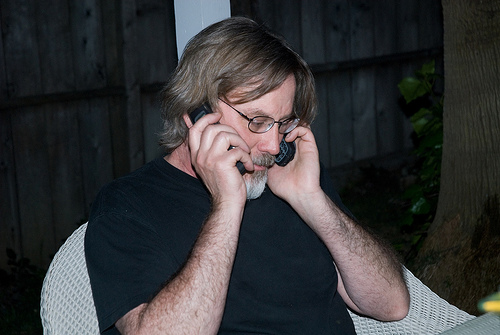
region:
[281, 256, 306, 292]
part of a shirt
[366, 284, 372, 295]
part of an arm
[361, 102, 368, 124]
part of a board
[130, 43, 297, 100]
man has brown hair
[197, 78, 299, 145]
man has black glasses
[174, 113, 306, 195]
man holds two phones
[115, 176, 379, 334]
man has black shirt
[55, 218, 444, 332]
man sits in white chair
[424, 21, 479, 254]
brown trunk of tree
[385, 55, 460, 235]
green leaves behind tree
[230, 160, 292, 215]
man has white beard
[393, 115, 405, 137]
part of a board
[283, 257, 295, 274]
part of a shirt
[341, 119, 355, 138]
part of a board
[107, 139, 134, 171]
edge of a board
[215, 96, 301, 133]
black frame reading glasses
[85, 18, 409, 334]
the man is using his 2 mobile phones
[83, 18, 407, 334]
the man is talking on his celphones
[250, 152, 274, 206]
the man has a mustache and a beard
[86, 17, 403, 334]
the man is wearing a black t shirt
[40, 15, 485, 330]
the man is sitting on the white chair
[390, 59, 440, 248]
green leaf plants on the ground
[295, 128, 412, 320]
white hairy arm of a man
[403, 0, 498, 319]
truck of a tree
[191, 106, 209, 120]
a black telephone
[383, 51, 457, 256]
green leaves behind tree trunk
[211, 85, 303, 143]
eye glasses on man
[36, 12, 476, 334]
man sitting in chair and holding one cell phone to each ear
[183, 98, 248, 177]
black cell phone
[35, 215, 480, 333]
white wicker chair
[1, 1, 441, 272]
brown wood slat fence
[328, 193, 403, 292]
brown hair on man's arm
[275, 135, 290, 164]
black buttons on face of cell phone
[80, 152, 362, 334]
black short sleeve t-shirt on man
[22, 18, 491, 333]
a man on the phone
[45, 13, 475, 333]
a person sitting down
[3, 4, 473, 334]
a scene outside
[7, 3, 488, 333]
a scene during the night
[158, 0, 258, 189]
a white post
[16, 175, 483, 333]
a white chair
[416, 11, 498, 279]
a tree in the background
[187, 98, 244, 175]
person holding black cell phone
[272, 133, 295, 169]
person holding black cell phone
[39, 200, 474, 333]
white wicker chair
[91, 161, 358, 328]
short sleeve black shirt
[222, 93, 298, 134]
black wire rimmed glasses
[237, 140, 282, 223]
white and brown beard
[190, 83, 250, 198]
black phone in hand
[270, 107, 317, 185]
black phone in hand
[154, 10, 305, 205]
shaggy brown hair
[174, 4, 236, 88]
white square post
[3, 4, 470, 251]
brown wooden fence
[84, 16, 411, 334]
white man on phone sitting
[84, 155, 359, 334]
short sleeved black cloth shirt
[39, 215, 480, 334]
large white cloth chair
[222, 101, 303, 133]
large wide black glasses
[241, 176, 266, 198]
small short grey beard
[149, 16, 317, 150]
large long blonde hair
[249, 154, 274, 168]
long wide blonde mustache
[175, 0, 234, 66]
thick white painted line